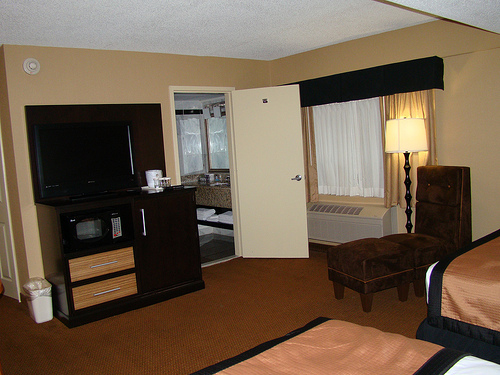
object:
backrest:
[413, 164, 472, 240]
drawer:
[70, 271, 138, 311]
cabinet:
[45, 202, 199, 319]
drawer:
[68, 246, 138, 282]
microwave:
[63, 209, 124, 245]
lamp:
[384, 118, 429, 236]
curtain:
[313, 102, 382, 197]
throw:
[189, 318, 465, 375]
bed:
[184, 318, 499, 375]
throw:
[426, 225, 500, 337]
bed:
[413, 226, 500, 348]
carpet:
[0, 240, 437, 373]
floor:
[0, 235, 428, 373]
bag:
[22, 277, 54, 321]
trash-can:
[28, 294, 53, 324]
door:
[135, 195, 206, 305]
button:
[446, 184, 451, 191]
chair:
[386, 166, 470, 299]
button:
[427, 180, 431, 188]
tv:
[32, 120, 136, 199]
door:
[229, 85, 311, 260]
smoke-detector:
[23, 55, 42, 76]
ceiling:
[4, 2, 400, 27]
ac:
[306, 200, 390, 245]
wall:
[393, 57, 499, 234]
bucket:
[144, 170, 162, 188]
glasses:
[158, 177, 171, 188]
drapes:
[304, 107, 316, 199]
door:
[1, 164, 29, 303]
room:
[0, 56, 500, 374]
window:
[303, 98, 386, 199]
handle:
[291, 173, 304, 184]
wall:
[0, 54, 169, 104]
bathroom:
[174, 95, 231, 262]